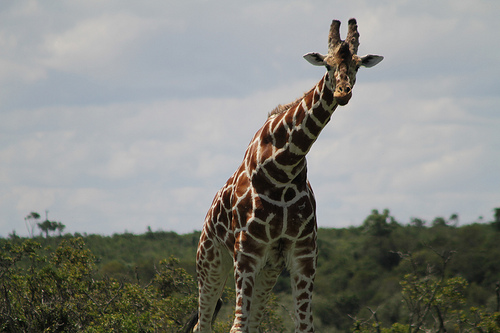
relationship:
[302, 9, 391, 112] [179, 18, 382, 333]
head of brown giraffe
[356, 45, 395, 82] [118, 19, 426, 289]
ear of giraffe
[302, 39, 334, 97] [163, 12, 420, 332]
ear of giraffe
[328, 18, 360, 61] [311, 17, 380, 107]
horns on head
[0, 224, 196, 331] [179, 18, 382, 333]
bush next to brown giraffe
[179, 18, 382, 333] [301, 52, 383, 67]
brown giraffe has two ears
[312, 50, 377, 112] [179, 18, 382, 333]
face of brown giraffe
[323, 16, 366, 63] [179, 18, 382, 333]
horns on brown giraffe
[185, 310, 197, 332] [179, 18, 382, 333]
tail end sticking out from brown giraffe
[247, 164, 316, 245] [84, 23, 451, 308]
spots on giraffe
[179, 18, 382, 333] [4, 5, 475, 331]
brown giraffe at safari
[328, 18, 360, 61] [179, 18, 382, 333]
horns of brown giraffe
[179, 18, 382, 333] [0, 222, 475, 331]
brown giraffe standing in area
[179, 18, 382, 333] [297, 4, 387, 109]
brown giraffe has head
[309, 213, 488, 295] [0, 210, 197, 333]
grass next bush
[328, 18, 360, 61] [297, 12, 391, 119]
horns on head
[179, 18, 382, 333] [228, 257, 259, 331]
brown giraffe has leg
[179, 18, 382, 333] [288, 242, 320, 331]
brown giraffe has leg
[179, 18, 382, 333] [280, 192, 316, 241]
brown giraffe has spot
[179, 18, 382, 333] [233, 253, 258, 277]
brown giraffe has spot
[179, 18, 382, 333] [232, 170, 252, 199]
brown giraffe has spot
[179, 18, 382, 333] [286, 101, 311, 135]
brown giraffe has spot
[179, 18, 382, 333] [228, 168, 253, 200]
brown giraffe has spot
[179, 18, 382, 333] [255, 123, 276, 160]
brown giraffe has brown spot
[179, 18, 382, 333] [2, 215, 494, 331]
brown giraffe in wild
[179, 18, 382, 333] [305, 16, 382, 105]
brown giraffe has head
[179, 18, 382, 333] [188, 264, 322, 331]
brown giraffe has legs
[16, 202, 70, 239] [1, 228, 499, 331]
tree in grass field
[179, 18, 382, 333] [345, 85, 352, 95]
brown giraffe has nostril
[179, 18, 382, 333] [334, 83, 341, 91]
brown giraffe has nostril